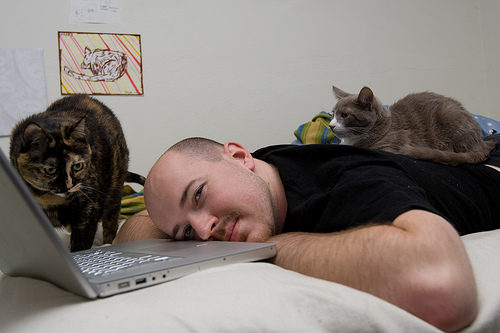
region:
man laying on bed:
[129, 126, 499, 315]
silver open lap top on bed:
[0, 97, 276, 314]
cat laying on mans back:
[310, 73, 498, 163]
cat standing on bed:
[7, 65, 133, 256]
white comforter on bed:
[140, 214, 499, 331]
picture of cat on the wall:
[40, 12, 160, 100]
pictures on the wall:
[0, 0, 170, 152]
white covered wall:
[157, 18, 498, 121]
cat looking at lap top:
[11, 79, 151, 262]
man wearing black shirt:
[248, 116, 498, 243]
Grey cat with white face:
[315, 80, 492, 171]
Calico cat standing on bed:
[0, 80, 176, 267]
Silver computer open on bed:
[2, 103, 294, 313]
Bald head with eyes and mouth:
[130, 124, 301, 268]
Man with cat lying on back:
[140, 118, 498, 330]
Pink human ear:
[222, 131, 263, 172]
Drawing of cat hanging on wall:
[47, 21, 172, 119]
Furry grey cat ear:
[347, 76, 390, 111]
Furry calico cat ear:
[61, 102, 99, 149]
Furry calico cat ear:
[15, 113, 49, 158]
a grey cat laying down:
[328, 82, 495, 167]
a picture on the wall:
[58, 27, 147, 99]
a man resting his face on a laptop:
[115, 122, 298, 264]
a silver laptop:
[1, 142, 280, 310]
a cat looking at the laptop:
[2, 94, 149, 301]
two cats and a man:
[13, 75, 490, 321]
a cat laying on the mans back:
[271, 71, 496, 227]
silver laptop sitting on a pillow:
[0, 125, 441, 330]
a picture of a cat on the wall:
[42, 25, 156, 95]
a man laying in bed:
[67, 110, 498, 327]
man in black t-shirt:
[109, 136, 499, 331]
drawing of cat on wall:
[57, 29, 142, 98]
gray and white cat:
[328, 83, 491, 160]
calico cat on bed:
[10, 96, 147, 253]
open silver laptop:
[0, 146, 278, 301]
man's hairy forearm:
[265, 208, 480, 331]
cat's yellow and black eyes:
[35, 160, 87, 175]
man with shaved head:
[109, 136, 499, 331]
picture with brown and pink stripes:
[57, 29, 144, 96]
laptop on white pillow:
[0, 152, 445, 332]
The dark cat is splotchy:
[9, 93, 129, 250]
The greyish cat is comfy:
[324, 83, 491, 163]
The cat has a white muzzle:
[329, 84, 495, 165]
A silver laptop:
[0, 150, 280, 300]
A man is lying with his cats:
[11, 85, 498, 332]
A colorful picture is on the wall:
[0, 0, 495, 205]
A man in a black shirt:
[110, 135, 499, 330]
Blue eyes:
[177, 175, 215, 245]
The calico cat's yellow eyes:
[35, 159, 89, 179]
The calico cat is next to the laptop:
[1, 95, 273, 298]